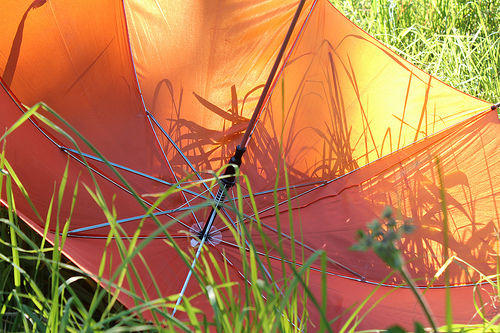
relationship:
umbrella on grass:
[48, 26, 475, 264] [391, 11, 497, 85]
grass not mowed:
[391, 11, 497, 85] [411, 6, 486, 102]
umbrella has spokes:
[48, 26, 475, 264] [148, 129, 326, 245]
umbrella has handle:
[48, 26, 475, 264] [235, 43, 274, 199]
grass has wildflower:
[391, 11, 497, 85] [363, 215, 449, 330]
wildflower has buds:
[363, 215, 449, 330] [385, 214, 413, 232]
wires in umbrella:
[65, 126, 371, 280] [48, 26, 475, 264]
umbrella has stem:
[48, 26, 475, 264] [225, 143, 247, 187]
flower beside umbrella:
[363, 215, 449, 330] [48, 26, 475, 264]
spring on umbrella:
[217, 186, 226, 205] [48, 26, 475, 264]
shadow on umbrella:
[211, 43, 422, 164] [48, 26, 475, 264]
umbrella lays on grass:
[48, 26, 475, 264] [391, 11, 497, 85]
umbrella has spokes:
[48, 26, 475, 264] [111, 129, 354, 283]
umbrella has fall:
[48, 26, 475, 264] [16, 264, 462, 326]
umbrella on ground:
[48, 26, 475, 264] [9, 201, 482, 333]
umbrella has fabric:
[48, 26, 475, 264] [169, 18, 247, 87]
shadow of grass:
[211, 43, 422, 164] [391, 11, 497, 85]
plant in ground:
[363, 215, 449, 330] [9, 201, 482, 333]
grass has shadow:
[391, 11, 497, 85] [211, 43, 422, 164]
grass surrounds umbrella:
[391, 11, 497, 85] [48, 26, 475, 264]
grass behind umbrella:
[391, 11, 497, 85] [48, 26, 475, 264]